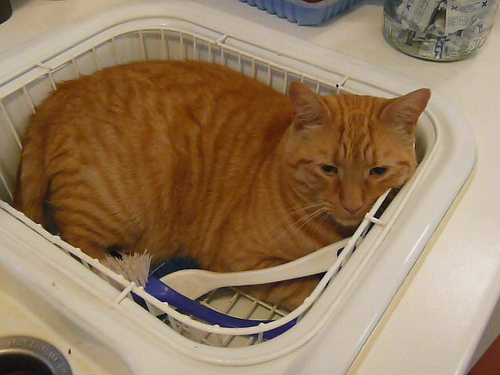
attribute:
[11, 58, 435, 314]
cat — orange, resting, striped, sleepy, comfortable, orange tabby, tabby, fuzzy, lying down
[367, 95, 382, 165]
stripe — orange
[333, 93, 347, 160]
stripe — orange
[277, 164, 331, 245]
stripe — orange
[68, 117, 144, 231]
stripe — orange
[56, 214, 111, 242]
stripe — orange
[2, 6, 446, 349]
sink rack — maybe dish rack, wire, dish drainer, metal wire, white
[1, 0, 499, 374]
counter — white, kitchen counter, older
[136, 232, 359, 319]
dish scrubber — white, blue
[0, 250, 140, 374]
left side — slightly grimy, left side of sink, yellowy, in need of scrub, maybe old [?]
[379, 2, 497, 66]
jar — clear, mason-type, *not* can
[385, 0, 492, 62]
inscrutable papers — blue, white, blue+white, packaged, inscrutable papers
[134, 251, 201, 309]
bristles — blue, *maybe* black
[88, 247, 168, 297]
bristles — white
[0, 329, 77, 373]
drain — circular, silvertone, metal, rubber, metal+rubber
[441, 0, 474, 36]
wipe — in package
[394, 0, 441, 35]
wipe — in package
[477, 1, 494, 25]
wipe — in package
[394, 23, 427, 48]
wipe — in package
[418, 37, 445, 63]
wipe — in package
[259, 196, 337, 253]
whiskers — right whiskers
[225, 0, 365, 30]
container — blue, tray [?]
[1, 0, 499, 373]
counter top — white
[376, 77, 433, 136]
ear — left ear, raised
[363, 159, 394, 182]
eye — left eye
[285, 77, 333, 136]
ear — right ear, raised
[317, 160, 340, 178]
eye — right eye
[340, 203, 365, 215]
nose — pink, pinkish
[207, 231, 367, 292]
long handle — white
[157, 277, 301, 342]
long handle — curved inward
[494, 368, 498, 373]
spoon — invisible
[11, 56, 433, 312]
fur — orange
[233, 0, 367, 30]
tray — blue, ruffled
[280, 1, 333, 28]
edge — ruffled, white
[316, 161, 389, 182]
eyes — dark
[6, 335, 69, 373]
writing — embossed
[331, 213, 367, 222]
mouth — little